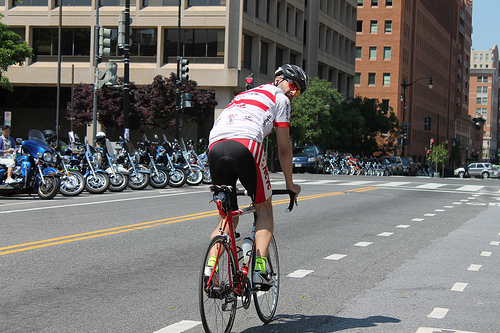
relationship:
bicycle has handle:
[197, 185, 297, 332] [229, 184, 301, 212]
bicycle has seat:
[197, 185, 297, 332] [209, 183, 239, 196]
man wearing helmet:
[203, 62, 308, 296] [273, 61, 309, 84]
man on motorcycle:
[3, 121, 20, 183] [1, 129, 60, 200]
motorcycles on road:
[53, 127, 208, 187] [3, 171, 498, 331]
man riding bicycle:
[203, 62, 308, 296] [192, 183, 301, 331]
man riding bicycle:
[203, 62, 308, 296] [197, 185, 297, 332]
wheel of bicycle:
[198, 231, 239, 331] [192, 183, 301, 331]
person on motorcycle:
[3, 121, 20, 183] [1, 129, 60, 200]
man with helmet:
[203, 62, 308, 296] [273, 61, 309, 84]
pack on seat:
[212, 191, 229, 216] [209, 183, 239, 196]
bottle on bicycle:
[212, 191, 229, 218] [197, 185, 297, 332]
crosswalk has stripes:
[215, 171, 498, 194] [381, 179, 444, 193]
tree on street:
[425, 145, 451, 179] [3, 171, 498, 331]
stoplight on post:
[427, 135, 438, 151] [429, 147, 433, 175]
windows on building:
[355, 43, 396, 64] [357, 1, 474, 176]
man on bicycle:
[203, 62, 308, 296] [197, 185, 297, 332]